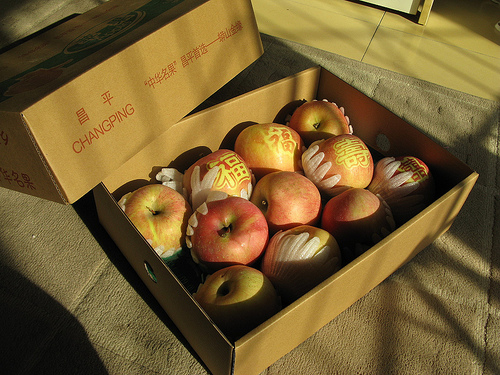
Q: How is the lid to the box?
A: Off.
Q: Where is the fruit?
A: In the box.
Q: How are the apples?
A: Gold and red.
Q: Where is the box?
A: On cement.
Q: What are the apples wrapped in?
A: Plastic.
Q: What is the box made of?
A: Cardboard.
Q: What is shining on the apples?
A: Sunlight.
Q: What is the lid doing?
A: Resting on corner.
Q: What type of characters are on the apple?
A: Asian.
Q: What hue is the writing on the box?
A: Red.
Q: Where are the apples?
A: In the box.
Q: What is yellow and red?
A: The apples.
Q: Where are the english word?
A: On the box.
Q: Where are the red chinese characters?
A: On the box.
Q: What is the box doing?
A: Holding apples.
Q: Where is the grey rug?
A: Under the box.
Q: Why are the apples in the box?
A: To keep organized.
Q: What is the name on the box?
A: Changping.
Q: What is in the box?
A: Apples.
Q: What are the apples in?
A: A box.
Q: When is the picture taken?
A: Daytime.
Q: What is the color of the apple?
A: Red.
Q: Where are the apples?
A: In the box.